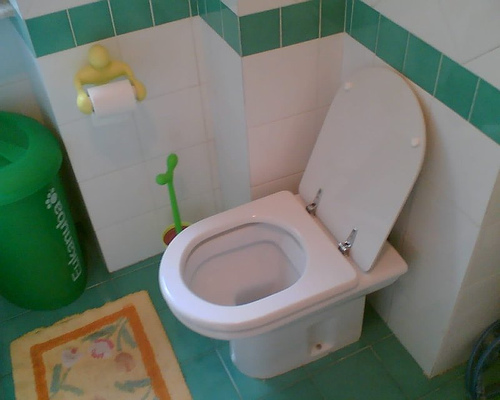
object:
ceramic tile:
[239, 7, 284, 57]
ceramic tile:
[280, 0, 319, 49]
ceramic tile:
[219, 1, 240, 55]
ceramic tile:
[67, 1, 116, 48]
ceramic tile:
[374, 11, 410, 75]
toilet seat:
[261, 258, 353, 296]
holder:
[70, 35, 148, 121]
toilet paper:
[83, 76, 139, 124]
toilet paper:
[73, 66, 175, 128]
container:
[0, 108, 98, 312]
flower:
[88, 322, 119, 366]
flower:
[106, 315, 142, 374]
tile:
[411, 95, 500, 225]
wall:
[240, 8, 315, 127]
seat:
[154, 187, 357, 342]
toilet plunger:
[153, 151, 195, 247]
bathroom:
[0, 0, 500, 398]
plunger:
[148, 152, 192, 245]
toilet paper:
[88, 76, 138, 116]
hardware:
[335, 224, 359, 257]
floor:
[206, 376, 326, 400]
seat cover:
[296, 65, 431, 271]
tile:
[132, 70, 209, 163]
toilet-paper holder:
[67, 45, 147, 113]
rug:
[7, 286, 192, 400]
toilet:
[154, 65, 432, 379]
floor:
[402, 378, 482, 400]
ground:
[238, 376, 479, 400]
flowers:
[42, 330, 92, 400]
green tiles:
[367, 9, 411, 75]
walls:
[3, 4, 496, 379]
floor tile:
[267, 350, 414, 398]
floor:
[14, 316, 153, 400]